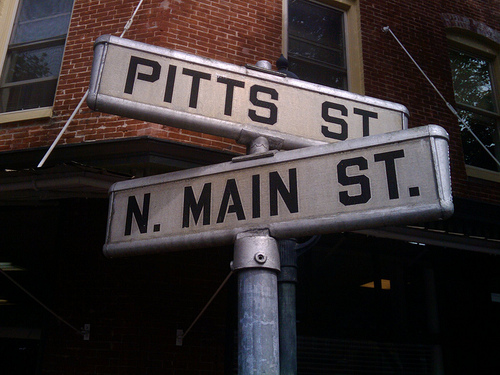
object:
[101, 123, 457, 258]
sign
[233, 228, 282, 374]
pole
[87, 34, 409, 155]
sign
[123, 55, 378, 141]
pitts st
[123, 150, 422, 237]
n. main st.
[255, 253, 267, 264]
bolt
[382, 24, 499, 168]
wire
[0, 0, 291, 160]
building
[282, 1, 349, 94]
window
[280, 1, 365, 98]
frame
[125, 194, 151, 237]
letter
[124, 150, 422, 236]
writing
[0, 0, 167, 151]
wall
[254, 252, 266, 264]
hole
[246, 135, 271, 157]
pole